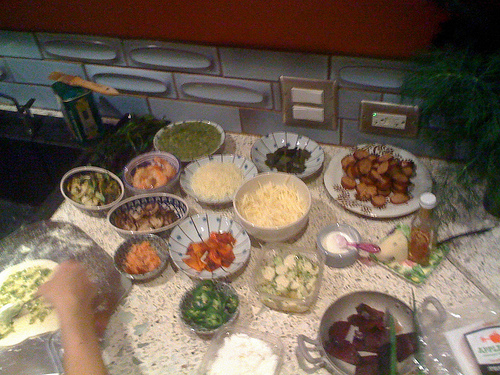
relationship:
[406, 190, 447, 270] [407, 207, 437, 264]
jar of condiment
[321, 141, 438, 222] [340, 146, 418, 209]
dish of sausage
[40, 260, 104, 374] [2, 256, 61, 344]
hand adding food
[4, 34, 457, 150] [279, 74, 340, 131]
panel with switches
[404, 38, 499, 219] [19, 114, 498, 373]
houseplant on table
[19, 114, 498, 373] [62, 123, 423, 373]
table with food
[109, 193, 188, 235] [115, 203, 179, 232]
bowl of mushrooms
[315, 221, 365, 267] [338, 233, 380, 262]
dish containing spoon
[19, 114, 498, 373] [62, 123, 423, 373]
table of food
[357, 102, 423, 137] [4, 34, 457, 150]
outlet on wall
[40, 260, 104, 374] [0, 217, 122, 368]
hand reaching at plate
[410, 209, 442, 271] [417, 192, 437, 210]
bottle with cap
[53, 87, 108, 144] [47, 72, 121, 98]
canister with brush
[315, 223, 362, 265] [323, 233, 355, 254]
bowl of cream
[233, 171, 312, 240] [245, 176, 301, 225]
bowl of cheese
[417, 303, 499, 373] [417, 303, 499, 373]
packaging food packaging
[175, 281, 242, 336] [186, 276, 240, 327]
bowl of jalapeno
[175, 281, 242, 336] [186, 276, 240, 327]
plate with jalapenos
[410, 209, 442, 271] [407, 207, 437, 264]
bottle of pepper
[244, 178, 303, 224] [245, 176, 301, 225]
white shredded cheese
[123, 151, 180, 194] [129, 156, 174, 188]
bowl of shrimp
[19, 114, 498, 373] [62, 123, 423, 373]
table of indredients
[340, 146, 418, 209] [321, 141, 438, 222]
food on plate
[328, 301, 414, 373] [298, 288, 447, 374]
food in bowl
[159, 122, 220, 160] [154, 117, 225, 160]
sauce in bowl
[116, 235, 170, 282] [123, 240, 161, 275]
bowl in food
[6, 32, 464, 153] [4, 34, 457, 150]
tiles on wall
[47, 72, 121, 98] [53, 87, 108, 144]
brush resting on can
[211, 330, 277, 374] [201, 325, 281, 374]
substance in clear container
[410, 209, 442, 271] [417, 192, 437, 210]
bottle with lid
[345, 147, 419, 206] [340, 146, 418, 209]
pieces of sausage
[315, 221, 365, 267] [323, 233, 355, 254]
bowl of dressing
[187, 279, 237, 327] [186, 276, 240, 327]
green sliced peppers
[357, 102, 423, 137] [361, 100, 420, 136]
outlets with silver plates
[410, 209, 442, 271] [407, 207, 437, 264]
bottle of sauce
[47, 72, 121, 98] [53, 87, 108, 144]
brush on can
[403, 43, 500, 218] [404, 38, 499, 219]
bushy green plant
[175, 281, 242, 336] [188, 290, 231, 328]
dish filled with slices